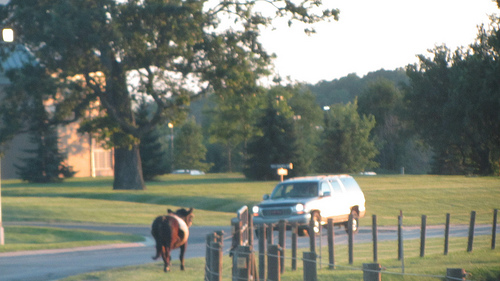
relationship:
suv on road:
[248, 170, 369, 237] [7, 256, 128, 263]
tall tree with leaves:
[22, 7, 199, 193] [149, 41, 180, 59]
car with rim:
[247, 174, 366, 234] [351, 217, 357, 229]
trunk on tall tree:
[102, 69, 147, 189] [0, 0, 279, 191]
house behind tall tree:
[1, 40, 116, 179] [0, 0, 279, 191]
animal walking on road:
[150, 207, 195, 273] [4, 247, 104, 279]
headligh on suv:
[285, 202, 309, 216] [251, 165, 391, 236]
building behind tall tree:
[3, 2, 120, 181] [0, 0, 279, 191]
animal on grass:
[147, 204, 195, 271] [46, 231, 499, 279]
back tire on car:
[344, 209, 361, 234] [245, 169, 367, 236]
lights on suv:
[253, 200, 310, 216] [251, 173, 365, 234]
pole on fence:
[489, 206, 499, 249] [203, 207, 499, 279]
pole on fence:
[206, 214, 500, 281] [203, 207, 499, 279]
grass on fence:
[88, 250, 500, 279] [203, 207, 499, 279]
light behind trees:
[3, 27, 13, 43] [0, 1, 499, 193]